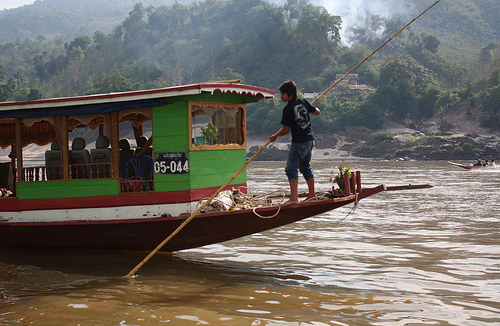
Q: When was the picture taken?
A: Daytime.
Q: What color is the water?
A: Brown.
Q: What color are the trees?
A: Green.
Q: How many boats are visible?
A: Two.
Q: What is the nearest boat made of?
A: Wood.